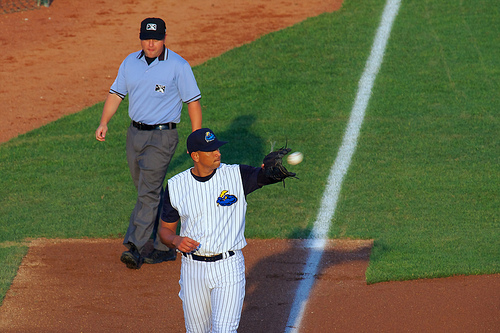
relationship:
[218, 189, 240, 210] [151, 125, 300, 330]
logo on player